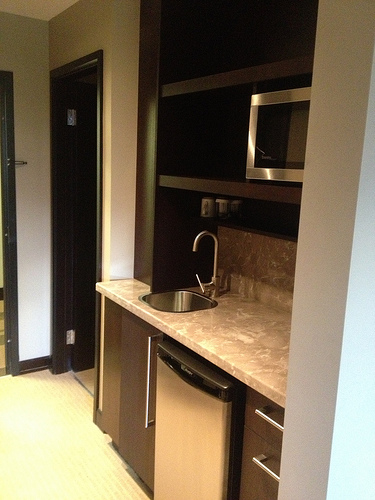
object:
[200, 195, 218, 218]
cup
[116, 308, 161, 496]
cabinet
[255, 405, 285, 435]
handle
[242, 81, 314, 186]
microwave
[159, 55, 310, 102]
shelf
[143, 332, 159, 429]
metal handle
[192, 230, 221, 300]
faucet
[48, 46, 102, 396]
door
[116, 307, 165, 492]
door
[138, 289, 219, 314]
sink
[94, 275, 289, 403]
counter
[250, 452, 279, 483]
handles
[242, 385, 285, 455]
drawer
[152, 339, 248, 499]
dishwasher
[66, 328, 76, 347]
hinge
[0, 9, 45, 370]
wall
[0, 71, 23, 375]
door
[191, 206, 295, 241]
shelf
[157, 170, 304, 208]
shelf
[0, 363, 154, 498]
floor